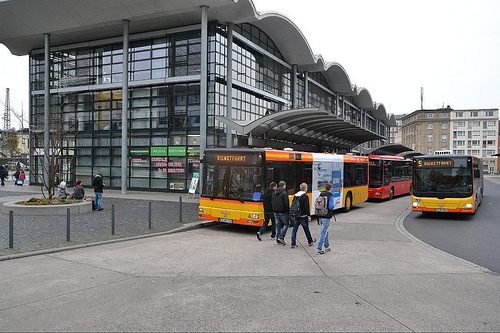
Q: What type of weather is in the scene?
A: It is cloudy.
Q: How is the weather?
A: It is cloudy.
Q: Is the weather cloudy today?
A: Yes, it is cloudy.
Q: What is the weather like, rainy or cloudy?
A: It is cloudy.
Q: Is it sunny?
A: No, it is cloudy.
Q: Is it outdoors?
A: Yes, it is outdoors.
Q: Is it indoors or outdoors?
A: It is outdoors.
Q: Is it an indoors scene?
A: No, it is outdoors.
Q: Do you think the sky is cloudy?
A: Yes, the sky is cloudy.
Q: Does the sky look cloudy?
A: Yes, the sky is cloudy.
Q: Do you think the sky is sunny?
A: No, the sky is cloudy.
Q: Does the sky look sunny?
A: No, the sky is cloudy.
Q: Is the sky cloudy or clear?
A: The sky is cloudy.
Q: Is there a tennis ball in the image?
A: No, there are no tennis balls.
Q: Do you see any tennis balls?
A: No, there are no tennis balls.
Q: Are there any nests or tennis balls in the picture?
A: No, there are no tennis balls or nests.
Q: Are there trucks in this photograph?
A: No, there are no trucks.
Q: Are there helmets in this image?
A: No, there are no helmets.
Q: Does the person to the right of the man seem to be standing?
A: Yes, the person is standing.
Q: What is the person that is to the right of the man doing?
A: The person is standing.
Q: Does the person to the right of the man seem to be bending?
A: No, the person is standing.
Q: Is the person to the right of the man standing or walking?
A: The person is standing.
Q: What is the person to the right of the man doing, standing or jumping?
A: The person is standing.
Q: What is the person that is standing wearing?
A: The person is wearing a backpack.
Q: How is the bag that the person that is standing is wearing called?
A: The bag is a backpack.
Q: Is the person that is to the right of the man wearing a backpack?
A: Yes, the person is wearing a backpack.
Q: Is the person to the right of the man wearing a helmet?
A: No, the person is wearing a backpack.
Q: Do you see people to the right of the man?
A: Yes, there is a person to the right of the man.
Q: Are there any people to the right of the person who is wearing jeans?
A: Yes, there is a person to the right of the man.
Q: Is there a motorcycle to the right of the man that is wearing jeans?
A: No, there is a person to the right of the man.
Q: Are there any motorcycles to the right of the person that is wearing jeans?
A: No, there is a person to the right of the man.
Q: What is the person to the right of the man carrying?
A: The person is carrying a backpack.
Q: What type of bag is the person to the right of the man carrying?
A: The person is carrying a backpack.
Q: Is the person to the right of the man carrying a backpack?
A: Yes, the person is carrying a backpack.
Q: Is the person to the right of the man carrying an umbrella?
A: No, the person is carrying a backpack.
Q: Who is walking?
A: The people are walking.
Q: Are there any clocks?
A: No, there are no clocks.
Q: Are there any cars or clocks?
A: No, there are no clocks or cars.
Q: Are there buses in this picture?
A: Yes, there is a bus.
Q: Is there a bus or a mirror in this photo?
A: Yes, there is a bus.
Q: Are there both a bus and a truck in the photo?
A: No, there is a bus but no trucks.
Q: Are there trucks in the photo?
A: No, there are no trucks.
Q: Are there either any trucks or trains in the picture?
A: No, there are no trucks or trains.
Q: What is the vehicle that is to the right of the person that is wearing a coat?
A: The vehicle is a bus.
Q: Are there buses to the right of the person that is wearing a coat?
A: Yes, there is a bus to the right of the person.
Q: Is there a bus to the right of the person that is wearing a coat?
A: Yes, there is a bus to the right of the person.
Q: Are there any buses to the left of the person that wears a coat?
A: No, the bus is to the right of the person.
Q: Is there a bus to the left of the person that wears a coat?
A: No, the bus is to the right of the person.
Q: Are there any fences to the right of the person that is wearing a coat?
A: No, there is a bus to the right of the person.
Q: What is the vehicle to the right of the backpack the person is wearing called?
A: The vehicle is a bus.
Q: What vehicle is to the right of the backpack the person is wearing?
A: The vehicle is a bus.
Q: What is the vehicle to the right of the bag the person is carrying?
A: The vehicle is a bus.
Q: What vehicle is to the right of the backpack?
A: The vehicle is a bus.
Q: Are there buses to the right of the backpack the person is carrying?
A: Yes, there is a bus to the right of the backpack.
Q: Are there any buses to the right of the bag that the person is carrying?
A: Yes, there is a bus to the right of the backpack.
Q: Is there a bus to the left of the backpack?
A: No, the bus is to the right of the backpack.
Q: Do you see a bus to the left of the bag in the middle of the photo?
A: No, the bus is to the right of the backpack.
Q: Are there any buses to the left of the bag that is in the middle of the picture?
A: No, the bus is to the right of the backpack.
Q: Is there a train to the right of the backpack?
A: No, there is a bus to the right of the backpack.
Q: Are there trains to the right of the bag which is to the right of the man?
A: No, there is a bus to the right of the backpack.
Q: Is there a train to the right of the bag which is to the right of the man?
A: No, there is a bus to the right of the backpack.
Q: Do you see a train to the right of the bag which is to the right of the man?
A: No, there is a bus to the right of the backpack.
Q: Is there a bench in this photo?
A: No, there are no benches.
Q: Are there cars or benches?
A: No, there are no benches or cars.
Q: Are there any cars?
A: No, there are no cars.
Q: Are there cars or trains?
A: No, there are no cars or trains.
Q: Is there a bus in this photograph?
A: Yes, there is a bus.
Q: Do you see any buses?
A: Yes, there is a bus.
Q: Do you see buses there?
A: Yes, there is a bus.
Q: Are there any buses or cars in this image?
A: Yes, there is a bus.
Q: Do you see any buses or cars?
A: Yes, there is a bus.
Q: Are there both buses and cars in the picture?
A: No, there is a bus but no cars.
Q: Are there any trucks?
A: No, there are no trucks.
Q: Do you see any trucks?
A: No, there are no trucks.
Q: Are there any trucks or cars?
A: No, there are no trucks or cars.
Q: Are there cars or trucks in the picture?
A: No, there are no trucks or cars.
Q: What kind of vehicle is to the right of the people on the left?
A: The vehicle is a bus.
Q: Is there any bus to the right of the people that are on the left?
A: Yes, there is a bus to the right of the people.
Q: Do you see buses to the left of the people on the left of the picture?
A: No, the bus is to the right of the people.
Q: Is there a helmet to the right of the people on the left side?
A: No, there is a bus to the right of the people.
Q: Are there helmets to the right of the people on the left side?
A: No, there is a bus to the right of the people.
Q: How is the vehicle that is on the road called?
A: The vehicle is a bus.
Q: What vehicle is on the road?
A: The vehicle is a bus.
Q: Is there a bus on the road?
A: Yes, there is a bus on the road.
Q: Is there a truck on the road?
A: No, there is a bus on the road.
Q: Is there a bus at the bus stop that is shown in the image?
A: Yes, there is a bus at the bus stop.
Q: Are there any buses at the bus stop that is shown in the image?
A: Yes, there is a bus at the bus stop.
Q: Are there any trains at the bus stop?
A: No, there is a bus at the bus stop.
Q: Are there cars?
A: No, there are no cars.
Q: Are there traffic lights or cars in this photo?
A: No, there are no cars or traffic lights.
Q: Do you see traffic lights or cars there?
A: No, there are no cars or traffic lights.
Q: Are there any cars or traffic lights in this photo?
A: No, there are no cars or traffic lights.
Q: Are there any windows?
A: Yes, there is a window.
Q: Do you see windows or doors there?
A: Yes, there is a window.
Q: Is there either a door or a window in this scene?
A: Yes, there is a window.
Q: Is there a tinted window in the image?
A: Yes, there is a tinted window.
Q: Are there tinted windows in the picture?
A: Yes, there is a tinted window.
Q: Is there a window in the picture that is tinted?
A: Yes, there is a window that is tinted.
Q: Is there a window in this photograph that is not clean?
A: Yes, there is a tinted window.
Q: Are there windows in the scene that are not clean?
A: Yes, there is a tinted window.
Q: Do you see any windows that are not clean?
A: Yes, there is a tinted window.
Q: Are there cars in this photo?
A: No, there are no cars.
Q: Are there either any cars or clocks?
A: No, there are no cars or clocks.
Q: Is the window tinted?
A: Yes, the window is tinted.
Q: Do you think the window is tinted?
A: Yes, the window is tinted.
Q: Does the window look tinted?
A: Yes, the window is tinted.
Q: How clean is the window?
A: The window is tinted.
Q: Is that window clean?
A: No, the window is tinted.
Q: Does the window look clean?
A: No, the window is tinted.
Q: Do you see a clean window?
A: No, there is a window but it is tinted.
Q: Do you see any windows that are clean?
A: No, there is a window but it is tinted.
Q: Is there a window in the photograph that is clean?
A: No, there is a window but it is tinted.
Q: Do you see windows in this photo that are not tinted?
A: No, there is a window but it is tinted.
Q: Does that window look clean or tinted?
A: The window is tinted.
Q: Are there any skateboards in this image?
A: No, there are no skateboards.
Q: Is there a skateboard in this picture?
A: No, there are no skateboards.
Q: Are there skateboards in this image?
A: No, there are no skateboards.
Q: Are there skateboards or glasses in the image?
A: No, there are no skateboards or glasses.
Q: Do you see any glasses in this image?
A: No, there are no glasses.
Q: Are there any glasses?
A: No, there are no glasses.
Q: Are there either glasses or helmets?
A: No, there are no glasses or helmets.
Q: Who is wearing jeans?
A: The man is wearing jeans.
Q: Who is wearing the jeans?
A: The man is wearing jeans.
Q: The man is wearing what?
A: The man is wearing jeans.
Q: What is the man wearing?
A: The man is wearing jeans.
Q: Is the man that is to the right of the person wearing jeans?
A: Yes, the man is wearing jeans.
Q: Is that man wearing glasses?
A: No, the man is wearing jeans.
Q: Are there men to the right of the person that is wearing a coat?
A: Yes, there is a man to the right of the person.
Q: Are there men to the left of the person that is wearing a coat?
A: No, the man is to the right of the person.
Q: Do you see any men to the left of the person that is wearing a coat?
A: No, the man is to the right of the person.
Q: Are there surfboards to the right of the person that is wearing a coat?
A: No, there is a man to the right of the person.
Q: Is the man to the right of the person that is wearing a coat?
A: Yes, the man is to the right of the person.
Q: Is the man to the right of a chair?
A: No, the man is to the right of the person.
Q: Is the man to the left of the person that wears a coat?
A: No, the man is to the right of the person.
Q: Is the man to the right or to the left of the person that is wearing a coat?
A: The man is to the right of the person.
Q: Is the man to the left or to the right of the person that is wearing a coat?
A: The man is to the right of the person.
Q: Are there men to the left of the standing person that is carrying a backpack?
A: Yes, there is a man to the left of the person.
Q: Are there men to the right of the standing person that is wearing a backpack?
A: No, the man is to the left of the person.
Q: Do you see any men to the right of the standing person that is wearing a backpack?
A: No, the man is to the left of the person.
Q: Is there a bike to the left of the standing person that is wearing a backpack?
A: No, there is a man to the left of the person.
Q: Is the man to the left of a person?
A: Yes, the man is to the left of a person.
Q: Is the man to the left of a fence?
A: No, the man is to the left of a person.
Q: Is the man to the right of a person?
A: No, the man is to the left of a person.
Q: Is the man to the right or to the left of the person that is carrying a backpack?
A: The man is to the left of the person.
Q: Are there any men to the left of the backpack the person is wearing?
A: Yes, there is a man to the left of the backpack.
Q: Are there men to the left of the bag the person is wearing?
A: Yes, there is a man to the left of the backpack.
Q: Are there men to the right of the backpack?
A: No, the man is to the left of the backpack.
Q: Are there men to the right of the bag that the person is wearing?
A: No, the man is to the left of the backpack.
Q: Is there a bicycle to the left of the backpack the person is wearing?
A: No, there is a man to the left of the backpack.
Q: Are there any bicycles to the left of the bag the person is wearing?
A: No, there is a man to the left of the backpack.